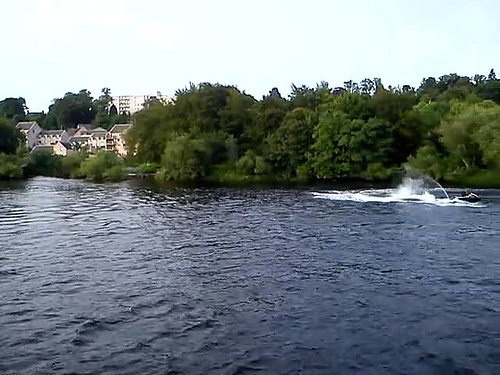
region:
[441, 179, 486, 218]
a jet ski driven alone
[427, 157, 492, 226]
a jet ski driven alone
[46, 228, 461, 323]
water in a lake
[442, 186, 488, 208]
wave runner in the lake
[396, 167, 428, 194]
water splashing from wave runner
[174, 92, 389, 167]
green trees by lake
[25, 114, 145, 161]
buildings on side of lake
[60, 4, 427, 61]
blue cloudy sky in the distance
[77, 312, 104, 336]
ripple in the lake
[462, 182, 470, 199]
person riding the wave runner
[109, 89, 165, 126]
tan building in the background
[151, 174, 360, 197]
edge of a lake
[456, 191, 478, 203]
jet ski in water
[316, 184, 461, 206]
wave from jet ski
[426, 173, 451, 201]
water spray from jet ski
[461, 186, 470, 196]
person riding jet ski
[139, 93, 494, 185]
trees next to lake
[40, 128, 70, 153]
house next to lake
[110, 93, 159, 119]
hotel by green trees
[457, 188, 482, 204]
jet ski in lake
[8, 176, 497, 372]
lake next to trees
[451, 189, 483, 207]
boat riding in lake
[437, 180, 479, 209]
A water ski.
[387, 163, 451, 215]
A water sprout from water ski.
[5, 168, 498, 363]
A blue lake.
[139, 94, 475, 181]
A line of trees along a lake.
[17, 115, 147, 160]
A group of buildings overlooking lake.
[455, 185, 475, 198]
A person riding a water ski.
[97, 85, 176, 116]
A large building on a hill.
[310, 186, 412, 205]
White foam on top of water.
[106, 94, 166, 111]
A white building in the distance.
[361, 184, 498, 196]
A wave in the water.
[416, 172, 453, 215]
Stream of water shooting upwards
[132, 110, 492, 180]
Thick, greenery lines water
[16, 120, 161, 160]
Houses near the water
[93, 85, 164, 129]
Tall, white building in background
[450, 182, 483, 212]
Jet ski in the water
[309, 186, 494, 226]
Jet ski causing ripples in water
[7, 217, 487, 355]
Water has a dark tint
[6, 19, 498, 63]
Sky is clear of clouds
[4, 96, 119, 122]
Dark green trees near building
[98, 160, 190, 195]
Opening in the greenery